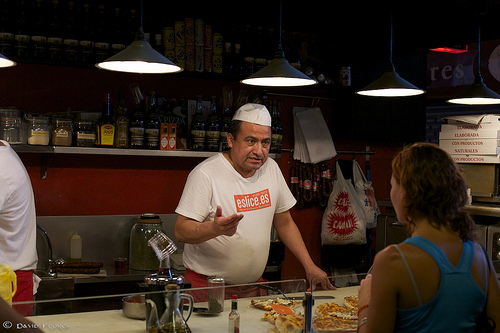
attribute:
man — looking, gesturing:
[172, 103, 335, 300]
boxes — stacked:
[433, 100, 498, 172]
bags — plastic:
[322, 156, 380, 246]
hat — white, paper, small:
[227, 99, 272, 127]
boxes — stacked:
[433, 127, 499, 146]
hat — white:
[230, 102, 270, 123]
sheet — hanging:
[297, 101, 339, 168]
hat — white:
[227, 95, 275, 129]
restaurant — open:
[17, 41, 487, 301]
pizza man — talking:
[167, 98, 340, 297]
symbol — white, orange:
[227, 187, 278, 218]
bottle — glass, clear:
[142, 282, 194, 332]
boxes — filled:
[432, 112, 497, 162]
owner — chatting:
[176, 111, 341, 301]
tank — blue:
[387, 219, 489, 333]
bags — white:
[310, 156, 399, 258]